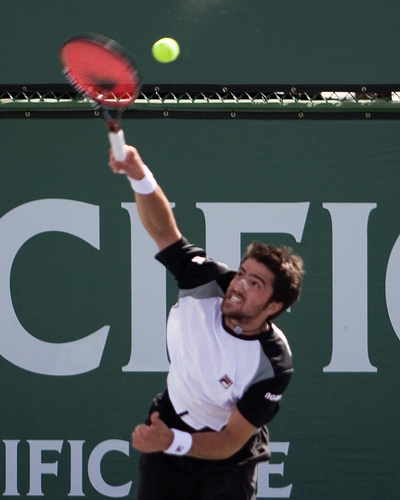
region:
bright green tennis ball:
[143, 28, 192, 74]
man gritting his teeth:
[204, 229, 320, 341]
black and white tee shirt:
[137, 230, 303, 454]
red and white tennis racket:
[44, 16, 151, 186]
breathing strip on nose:
[228, 270, 258, 296]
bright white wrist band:
[153, 418, 203, 463]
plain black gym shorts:
[115, 381, 282, 498]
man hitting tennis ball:
[48, 38, 322, 499]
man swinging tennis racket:
[49, 26, 351, 499]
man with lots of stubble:
[202, 229, 319, 339]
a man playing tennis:
[175, 214, 289, 471]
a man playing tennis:
[152, 262, 249, 485]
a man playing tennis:
[183, 356, 241, 483]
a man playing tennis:
[199, 281, 276, 465]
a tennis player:
[26, 28, 318, 490]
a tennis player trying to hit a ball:
[46, 24, 310, 481]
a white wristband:
[165, 421, 193, 463]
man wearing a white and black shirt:
[132, 240, 300, 433]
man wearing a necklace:
[220, 316, 266, 340]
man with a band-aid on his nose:
[238, 273, 251, 297]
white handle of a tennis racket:
[104, 124, 136, 176]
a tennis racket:
[49, 24, 149, 160]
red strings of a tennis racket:
[68, 37, 136, 102]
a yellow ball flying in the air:
[144, 32, 197, 71]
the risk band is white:
[178, 439, 183, 449]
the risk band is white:
[179, 439, 181, 448]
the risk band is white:
[179, 439, 186, 456]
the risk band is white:
[179, 432, 181, 448]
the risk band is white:
[175, 437, 183, 454]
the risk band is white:
[177, 440, 185, 458]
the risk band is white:
[179, 438, 185, 452]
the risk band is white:
[177, 433, 188, 451]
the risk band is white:
[179, 441, 187, 454]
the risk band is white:
[178, 435, 182, 453]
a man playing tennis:
[154, 224, 398, 499]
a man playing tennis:
[95, 238, 217, 482]